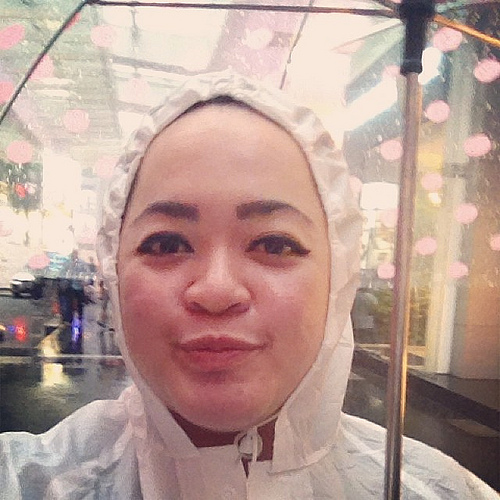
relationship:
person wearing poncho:
[0, 76, 500, 500] [26, 345, 448, 498]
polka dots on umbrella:
[425, 100, 488, 163] [43, 29, 494, 323]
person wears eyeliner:
[0, 76, 500, 500] [248, 234, 299, 244]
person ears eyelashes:
[0, 76, 500, 500] [245, 233, 310, 248]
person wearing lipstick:
[0, 76, 500, 500] [194, 353, 235, 360]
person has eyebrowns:
[0, 76, 500, 500] [129, 183, 319, 232]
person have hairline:
[0, 76, 500, 500] [158, 111, 286, 125]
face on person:
[131, 163, 322, 364] [0, 76, 500, 500]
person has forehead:
[0, 76, 500, 500] [168, 112, 279, 179]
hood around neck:
[72, 358, 361, 487] [150, 412, 291, 461]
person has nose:
[0, 76, 500, 500] [176, 267, 263, 318]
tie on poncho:
[233, 426, 269, 468] [0, 67, 500, 499]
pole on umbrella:
[400, 65, 421, 365] [43, 29, 494, 323]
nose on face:
[176, 267, 263, 318] [131, 163, 322, 364]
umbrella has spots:
[43, 29, 494, 323] [19, 109, 110, 182]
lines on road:
[34, 342, 125, 376] [63, 292, 125, 411]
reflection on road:
[46, 304, 98, 379] [63, 292, 125, 411]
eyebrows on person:
[115, 196, 321, 229] [162, 84, 362, 371]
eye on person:
[129, 227, 213, 274] [162, 84, 362, 371]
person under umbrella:
[162, 84, 362, 371] [43, 29, 494, 323]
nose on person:
[176, 267, 263, 318] [162, 84, 362, 371]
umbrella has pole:
[43, 29, 494, 323] [400, 65, 421, 365]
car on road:
[19, 250, 77, 303] [63, 292, 125, 411]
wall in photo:
[454, 162, 495, 380] [48, 52, 478, 473]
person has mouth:
[162, 84, 362, 371] [156, 326, 274, 369]